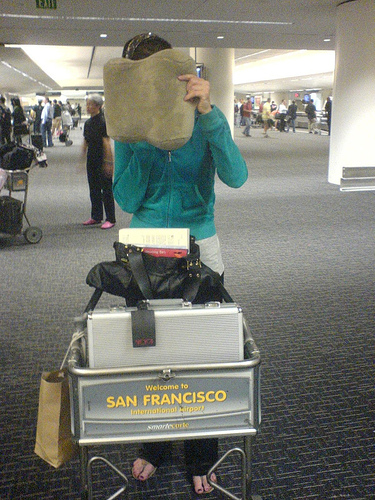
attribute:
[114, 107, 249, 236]
sweater — zip up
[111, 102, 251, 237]
fabric — blue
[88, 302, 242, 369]
carry case — large, metal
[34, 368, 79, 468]
paper bag — brown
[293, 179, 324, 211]
floor — carpeted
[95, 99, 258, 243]
jacket — teal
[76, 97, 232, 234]
shirt — blue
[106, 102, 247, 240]
shirt — blue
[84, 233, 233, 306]
purse — black, leather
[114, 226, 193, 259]
book — white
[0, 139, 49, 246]
luggage cart — full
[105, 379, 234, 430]
text — yellow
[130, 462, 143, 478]
toes — painted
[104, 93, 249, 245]
shirt — blue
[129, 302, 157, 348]
tag — black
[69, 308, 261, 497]
cart — grey